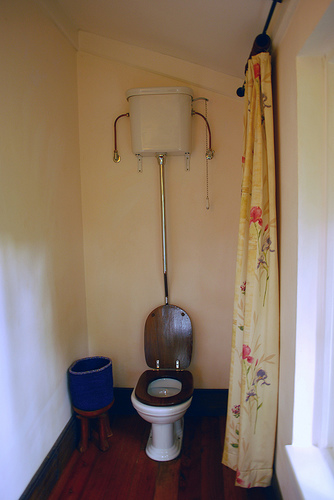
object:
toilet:
[113, 86, 214, 464]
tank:
[125, 86, 193, 155]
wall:
[0, 0, 274, 498]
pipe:
[155, 155, 168, 304]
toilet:
[131, 305, 194, 461]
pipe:
[113, 113, 129, 163]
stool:
[71, 399, 113, 453]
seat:
[135, 369, 195, 406]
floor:
[46, 416, 284, 499]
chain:
[205, 99, 211, 198]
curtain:
[221, 52, 280, 488]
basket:
[68, 356, 113, 411]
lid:
[143, 304, 192, 370]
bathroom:
[0, 0, 334, 499]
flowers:
[241, 344, 253, 364]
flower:
[245, 369, 270, 401]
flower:
[249, 206, 262, 227]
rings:
[245, 33, 272, 75]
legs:
[100, 416, 109, 452]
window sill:
[285, 444, 334, 499]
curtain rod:
[236, 0, 279, 97]